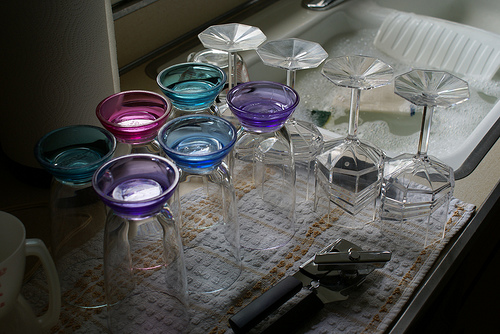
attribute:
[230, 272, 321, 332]
handle — black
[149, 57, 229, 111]
base — color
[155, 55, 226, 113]
glass — drinking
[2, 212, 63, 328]
coffee mug — white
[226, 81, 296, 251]
glass — clear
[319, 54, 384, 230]
glass — clear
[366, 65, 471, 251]
wine glas — clear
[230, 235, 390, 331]
can opener — black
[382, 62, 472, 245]
glass — white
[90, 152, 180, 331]
glass — drinking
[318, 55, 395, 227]
glass — clear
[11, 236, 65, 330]
handle — white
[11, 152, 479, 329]
towel — white, brown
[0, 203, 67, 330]
cup — white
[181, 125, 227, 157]
base — blue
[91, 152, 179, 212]
base — color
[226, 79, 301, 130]
base — purple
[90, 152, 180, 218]
base — purple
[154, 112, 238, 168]
base — blue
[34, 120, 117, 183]
base — green